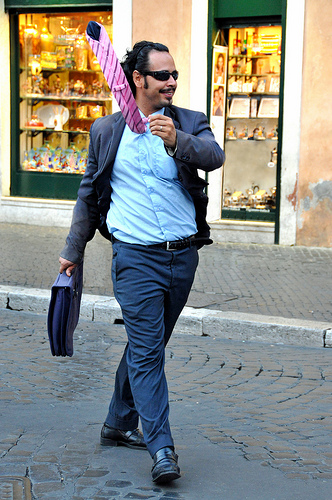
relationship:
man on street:
[58, 39, 225, 486] [174, 336, 327, 498]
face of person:
[132, 39, 187, 107] [42, 22, 233, 482]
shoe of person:
[150, 446, 182, 484] [42, 22, 233, 482]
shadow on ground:
[157, 474, 180, 497] [0, 249, 319, 495]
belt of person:
[151, 232, 213, 254] [42, 22, 233, 482]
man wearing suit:
[58, 39, 228, 484] [83, 112, 235, 276]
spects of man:
[136, 65, 182, 85] [58, 39, 228, 484]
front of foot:
[157, 465, 176, 475] [150, 445, 183, 484]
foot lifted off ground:
[150, 445, 183, 484] [5, 302, 330, 495]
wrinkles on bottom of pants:
[137, 403, 175, 453] [101, 241, 202, 457]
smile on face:
[155, 87, 174, 97] [137, 35, 182, 109]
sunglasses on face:
[139, 61, 180, 79] [144, 45, 179, 106]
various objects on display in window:
[17, 9, 111, 175] [5, 3, 127, 205]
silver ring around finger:
[157, 123, 164, 131] [148, 123, 170, 131]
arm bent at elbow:
[147, 106, 224, 167] [203, 143, 226, 173]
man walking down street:
[58, 39, 228, 484] [2, 221, 329, 497]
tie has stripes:
[83, 19, 153, 140] [101, 43, 120, 79]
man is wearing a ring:
[58, 39, 228, 484] [159, 126, 163, 130]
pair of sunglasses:
[141, 68, 180, 79] [143, 68, 178, 80]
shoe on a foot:
[151, 446, 181, 482] [150, 445, 182, 481]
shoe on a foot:
[97, 420, 142, 450] [98, 421, 142, 449]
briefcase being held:
[43, 261, 84, 358] [56, 254, 77, 277]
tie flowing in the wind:
[85, 19, 151, 135] [6, 13, 239, 150]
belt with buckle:
[140, 232, 200, 254] [166, 239, 178, 252]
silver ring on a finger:
[159, 125, 163, 132] [149, 126, 171, 130]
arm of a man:
[55, 116, 111, 276] [58, 39, 228, 484]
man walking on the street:
[58, 39, 228, 484] [6, 307, 321, 491]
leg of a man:
[108, 252, 185, 481] [58, 39, 228, 484]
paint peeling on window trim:
[253, 158, 323, 223] [271, 0, 309, 245]